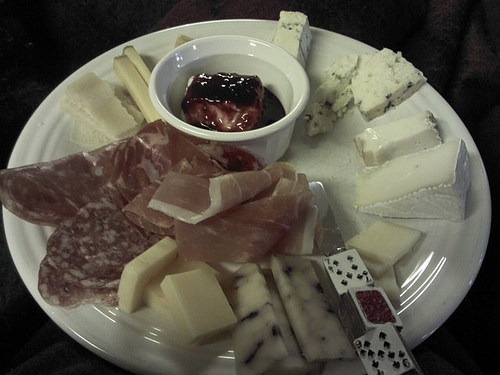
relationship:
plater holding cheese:
[317, 58, 486, 275] [306, 72, 390, 145]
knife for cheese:
[300, 182, 337, 227] [306, 72, 390, 145]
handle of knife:
[327, 262, 409, 354] [300, 182, 337, 227]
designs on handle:
[323, 255, 400, 315] [327, 262, 409, 354]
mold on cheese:
[321, 94, 371, 122] [306, 72, 390, 145]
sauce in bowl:
[194, 71, 245, 102] [138, 55, 210, 127]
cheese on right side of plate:
[306, 72, 390, 145] [10, 18, 484, 351]